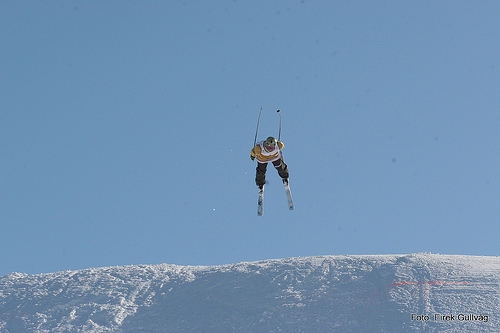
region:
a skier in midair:
[227, 98, 306, 226]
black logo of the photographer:
[399, 305, 499, 329]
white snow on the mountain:
[102, 264, 331, 317]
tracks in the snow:
[16, 263, 167, 323]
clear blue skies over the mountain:
[54, 78, 209, 234]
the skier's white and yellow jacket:
[252, 140, 285, 162]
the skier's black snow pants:
[246, 163, 299, 192]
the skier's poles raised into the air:
[231, 103, 297, 150]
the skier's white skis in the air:
[239, 180, 318, 223]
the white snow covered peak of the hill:
[1, 238, 488, 308]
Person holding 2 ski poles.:
[248, 125, 310, 175]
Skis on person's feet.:
[235, 187, 315, 222]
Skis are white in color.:
[236, 173, 317, 230]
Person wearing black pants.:
[248, 164, 302, 171]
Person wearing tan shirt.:
[248, 138, 294, 164]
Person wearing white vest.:
[259, 130, 279, 200]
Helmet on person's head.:
[263, 127, 289, 172]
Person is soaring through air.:
[168, 187, 369, 274]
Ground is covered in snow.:
[93, 249, 440, 329]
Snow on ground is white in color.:
[171, 260, 371, 328]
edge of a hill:
[369, 240, 406, 282]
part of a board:
[255, 200, 265, 212]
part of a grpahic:
[429, 298, 459, 328]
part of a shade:
[299, 278, 328, 328]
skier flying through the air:
[234, 80, 319, 237]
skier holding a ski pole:
[274, 103, 284, 152]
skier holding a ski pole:
[248, 100, 268, 155]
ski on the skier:
[276, 164, 303, 214]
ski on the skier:
[249, 180, 269, 220]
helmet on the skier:
[262, 133, 277, 155]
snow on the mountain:
[312, 260, 397, 320]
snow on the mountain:
[22, 278, 119, 328]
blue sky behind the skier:
[76, 64, 451, 107]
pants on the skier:
[252, 160, 299, 188]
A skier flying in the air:
[249, 104, 296, 216]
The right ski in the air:
[257, 203, 262, 215]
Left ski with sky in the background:
[287, 192, 294, 211]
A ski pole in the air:
[278, 115, 281, 138]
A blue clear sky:
[42, 28, 137, 60]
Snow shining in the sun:
[66, 271, 109, 288]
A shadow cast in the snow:
[185, 300, 230, 325]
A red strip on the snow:
[387, 280, 474, 285]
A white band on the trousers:
[278, 164, 282, 167]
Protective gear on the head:
[266, 135, 274, 145]